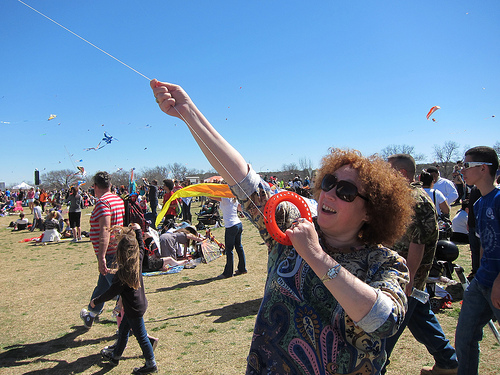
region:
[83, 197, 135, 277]
the shirt has stripes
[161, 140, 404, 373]
woman has sunglasses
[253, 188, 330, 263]
the object is red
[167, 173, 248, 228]
the kite is yellow and orange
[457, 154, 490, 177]
the sunglasses are white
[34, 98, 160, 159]
kites are in the air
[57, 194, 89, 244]
she has shorts on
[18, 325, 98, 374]
shadows are on the ground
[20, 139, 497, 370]
it is daylight outside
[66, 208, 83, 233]
shorts are black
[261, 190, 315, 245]
Red Rings with Holes in it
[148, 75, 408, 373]
Woman Holding onto her kite string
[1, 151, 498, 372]
Tons of people gathered together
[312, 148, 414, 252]
Womans Curly Brown Hair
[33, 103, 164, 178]
Couple of kites in the sky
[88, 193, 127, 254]
Red and white striped shirt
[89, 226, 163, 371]
Wind Blowing the little girls hair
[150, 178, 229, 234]
Long yellow and orange kite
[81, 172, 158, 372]
Father and daughter holding hands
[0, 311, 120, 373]
Shadows cast by little girl and father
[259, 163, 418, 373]
this is a lady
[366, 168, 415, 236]
this is the hair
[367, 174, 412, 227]
the hair is shaggy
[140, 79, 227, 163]
the hand is raised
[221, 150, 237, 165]
the lady is light skinned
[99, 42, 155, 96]
this is a rope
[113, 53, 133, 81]
the rope is thin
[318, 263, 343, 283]
this is a wrist watch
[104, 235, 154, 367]
the child is walking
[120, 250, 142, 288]
the hair is long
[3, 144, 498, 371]
large gathering of kite flyers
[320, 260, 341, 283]
kite flyer wearing a watch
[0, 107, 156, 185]
kites billowing through the air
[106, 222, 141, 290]
air being blown by harsh winds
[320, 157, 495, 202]
wearing glasses to protect against uv rays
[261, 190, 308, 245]
professional kite reel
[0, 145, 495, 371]
large gathering of people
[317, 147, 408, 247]
smile indicates having alot of fun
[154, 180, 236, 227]
yellow kite flying in wind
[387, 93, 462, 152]
a kite in the sky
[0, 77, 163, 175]
kites flying in the sky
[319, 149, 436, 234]
a woman with red hair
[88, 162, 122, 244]
a man wearing a striped shirt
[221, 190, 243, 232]
a girl wearing a white shirt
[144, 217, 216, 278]
a woman on the ground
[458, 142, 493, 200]
a young man wearing sunglasses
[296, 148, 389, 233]
a woman wearing sunglasses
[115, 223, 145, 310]
a young girl with long hair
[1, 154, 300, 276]
several people in a field